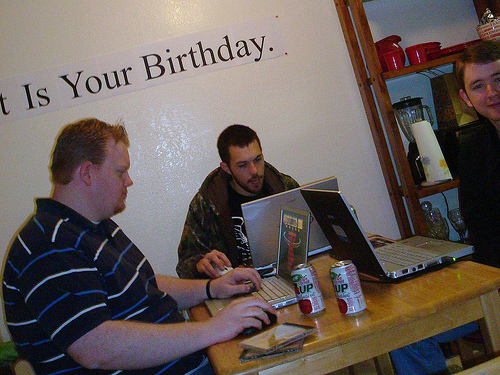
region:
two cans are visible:
[278, 257, 360, 355]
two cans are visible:
[274, 217, 388, 347]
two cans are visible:
[294, 250, 441, 374]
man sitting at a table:
[20, 126, 242, 346]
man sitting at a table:
[190, 122, 304, 250]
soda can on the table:
[285, 266, 327, 315]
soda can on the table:
[326, 265, 373, 341]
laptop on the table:
[307, 187, 463, 271]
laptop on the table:
[226, 212, 310, 315]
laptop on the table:
[242, 180, 343, 240]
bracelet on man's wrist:
[197, 275, 223, 300]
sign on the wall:
[2, 19, 289, 93]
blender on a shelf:
[394, 97, 434, 179]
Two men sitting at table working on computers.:
[0, 112, 310, 374]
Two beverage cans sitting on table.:
[288, 260, 370, 330]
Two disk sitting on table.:
[230, 318, 327, 360]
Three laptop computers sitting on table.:
[206, 176, 474, 319]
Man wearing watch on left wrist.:
[198, 275, 218, 301]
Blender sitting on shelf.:
[386, 91, 448, 195]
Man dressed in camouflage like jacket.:
[167, 152, 329, 284]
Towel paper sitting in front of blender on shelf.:
[408, 117, 461, 192]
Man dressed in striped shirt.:
[5, 201, 215, 373]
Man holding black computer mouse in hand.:
[227, 299, 281, 338]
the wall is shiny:
[129, 87, 194, 204]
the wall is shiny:
[112, 131, 335, 364]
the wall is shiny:
[75, 111, 235, 227]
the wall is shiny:
[142, 141, 193, 171]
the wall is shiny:
[102, 23, 182, 118]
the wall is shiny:
[145, 96, 240, 249]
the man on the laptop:
[4, 109, 280, 373]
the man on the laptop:
[188, 117, 358, 268]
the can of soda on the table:
[309, 256, 382, 318]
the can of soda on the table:
[279, 262, 329, 316]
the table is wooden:
[189, 222, 496, 374]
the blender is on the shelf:
[388, 92, 445, 190]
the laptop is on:
[194, 203, 332, 314]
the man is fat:
[3, 115, 275, 367]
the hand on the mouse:
[214, 292, 279, 343]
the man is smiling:
[432, 41, 497, 274]